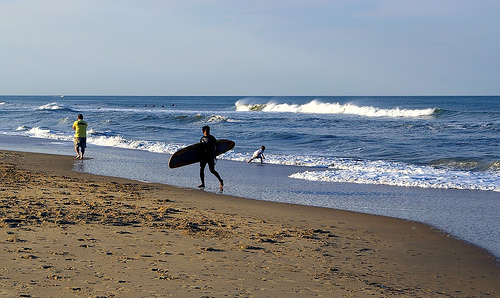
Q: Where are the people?
A: Beach.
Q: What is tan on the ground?
A: Sand.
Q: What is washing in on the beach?
A: Waves.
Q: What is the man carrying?
A: Surfboard.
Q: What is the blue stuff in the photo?
A: Water.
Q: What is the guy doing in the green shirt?
A: Walking.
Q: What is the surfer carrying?
A: Surfboard.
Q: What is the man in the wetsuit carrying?
A: Surfboard.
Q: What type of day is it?
A: Cloudy.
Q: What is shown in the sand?
A: Footprints.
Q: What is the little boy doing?
A: Playing in the water.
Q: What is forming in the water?
A: Wave.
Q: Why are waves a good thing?
A: So surfers can surf.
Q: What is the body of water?
A: Ocean.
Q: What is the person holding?
A: Surfboard.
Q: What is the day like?
A: Sunny.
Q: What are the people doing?
A: Enjoying the beach.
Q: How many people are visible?
A: Three.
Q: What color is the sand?
A: Brown.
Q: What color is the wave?
A: White.